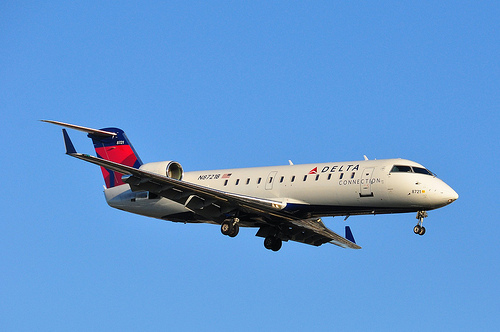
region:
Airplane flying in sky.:
[10, 102, 472, 259]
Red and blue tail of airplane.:
[80, 122, 151, 189]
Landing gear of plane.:
[405, 208, 435, 241]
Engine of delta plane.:
[135, 159, 185, 189]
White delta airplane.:
[42, 109, 460, 260]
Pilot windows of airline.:
[377, 163, 442, 180]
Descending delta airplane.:
[37, 104, 462, 259]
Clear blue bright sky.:
[0, 1, 495, 121]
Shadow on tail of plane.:
[102, 151, 142, 193]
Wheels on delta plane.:
[219, 218, 284, 252]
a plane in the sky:
[44, 95, 454, 278]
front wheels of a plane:
[409, 213, 431, 238]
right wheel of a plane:
[216, 218, 243, 240]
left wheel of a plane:
[257, 236, 289, 252]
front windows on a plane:
[390, 166, 427, 173]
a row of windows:
[228, 170, 358, 187]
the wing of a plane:
[53, 131, 228, 196]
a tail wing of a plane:
[35, 118, 129, 135]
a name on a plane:
[312, 161, 364, 178]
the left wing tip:
[328, 228, 364, 250]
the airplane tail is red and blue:
[87, 121, 144, 190]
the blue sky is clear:
[7, 10, 495, 112]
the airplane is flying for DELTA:
[42, 117, 461, 255]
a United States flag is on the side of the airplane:
[220, 163, 233, 184]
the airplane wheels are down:
[211, 212, 439, 256]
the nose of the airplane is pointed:
[419, 175, 467, 212]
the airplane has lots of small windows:
[217, 170, 361, 189]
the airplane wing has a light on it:
[102, 134, 231, 206]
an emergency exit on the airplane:
[263, 166, 280, 192]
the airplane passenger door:
[355, 163, 378, 202]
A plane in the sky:
[3, 1, 499, 330]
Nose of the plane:
[414, 151, 465, 219]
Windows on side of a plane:
[220, 165, 363, 188]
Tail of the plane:
[33, 115, 148, 184]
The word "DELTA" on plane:
[319, 161, 361, 175]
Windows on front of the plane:
[383, 156, 437, 180]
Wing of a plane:
[59, 122, 272, 220]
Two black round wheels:
[212, 214, 250, 244]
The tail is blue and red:
[88, 121, 144, 189]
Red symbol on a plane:
[302, 159, 322, 180]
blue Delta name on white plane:
[318, 161, 360, 173]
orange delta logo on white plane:
[304, 165, 318, 174]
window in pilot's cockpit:
[389, 163, 434, 175]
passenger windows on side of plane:
[221, 173, 354, 185]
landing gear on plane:
[413, 210, 425, 235]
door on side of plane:
[358, 166, 375, 196]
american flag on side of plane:
[221, 171, 231, 179]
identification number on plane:
[196, 173, 221, 180]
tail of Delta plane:
[38, 115, 143, 187]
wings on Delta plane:
[59, 130, 359, 247]